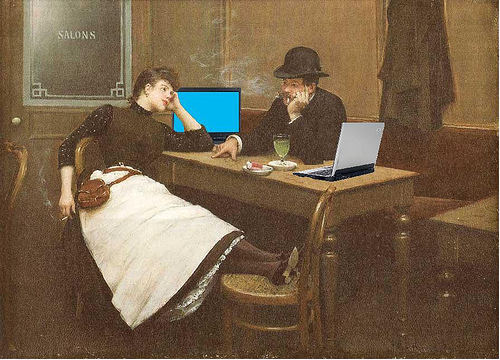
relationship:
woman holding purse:
[58, 64, 303, 327] [78, 161, 128, 211]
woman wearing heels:
[58, 64, 303, 327] [270, 231, 312, 288]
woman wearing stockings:
[58, 64, 303, 327] [233, 242, 275, 277]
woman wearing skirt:
[58, 64, 303, 327] [79, 171, 242, 330]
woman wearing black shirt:
[58, 64, 303, 327] [49, 99, 216, 189]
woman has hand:
[58, 64, 303, 327] [41, 172, 103, 233]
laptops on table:
[166, 85, 240, 145] [135, 128, 427, 331]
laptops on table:
[289, 115, 401, 185] [135, 128, 427, 331]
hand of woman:
[54, 192, 79, 224] [110, 62, 202, 165]